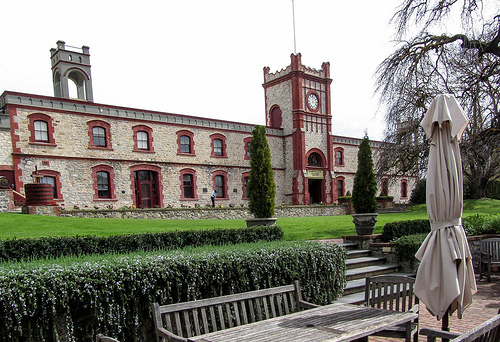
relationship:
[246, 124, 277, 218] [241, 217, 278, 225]
bush. in planter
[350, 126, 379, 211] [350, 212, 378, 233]
evergreen tree in planter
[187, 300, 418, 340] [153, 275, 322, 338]
table with bench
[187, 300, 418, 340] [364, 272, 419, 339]
table with chair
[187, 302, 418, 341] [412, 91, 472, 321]
table by umbrella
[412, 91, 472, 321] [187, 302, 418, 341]
umbrella by table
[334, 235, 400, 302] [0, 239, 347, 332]
stairs between flower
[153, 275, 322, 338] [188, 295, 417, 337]
bench at table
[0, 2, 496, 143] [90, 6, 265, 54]
sky has clouds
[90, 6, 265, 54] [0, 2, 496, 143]
clouds in the sky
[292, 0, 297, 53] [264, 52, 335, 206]
pole on tower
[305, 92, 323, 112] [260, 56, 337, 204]
clock is on tower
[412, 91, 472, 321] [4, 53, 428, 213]
umbrella is by building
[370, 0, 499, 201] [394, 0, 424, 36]
tree with branch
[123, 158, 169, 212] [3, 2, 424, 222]
window on building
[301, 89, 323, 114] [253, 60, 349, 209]
clock on tower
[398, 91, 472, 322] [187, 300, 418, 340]
umbrella next to table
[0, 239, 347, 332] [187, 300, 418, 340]
flower next to table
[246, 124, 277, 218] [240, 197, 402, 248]
bush. in pots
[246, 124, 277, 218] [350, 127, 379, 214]
bush. by evergreen tree